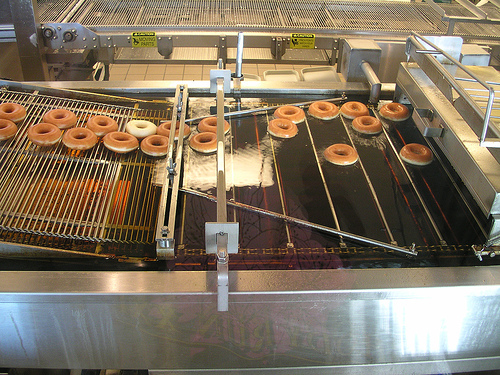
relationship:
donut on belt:
[125, 120, 157, 139] [13, 77, 190, 238]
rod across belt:
[199, 69, 236, 275] [2, 93, 472, 258]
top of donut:
[311, 99, 337, 115] [307, 99, 339, 121]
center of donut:
[114, 134, 131, 144] [101, 130, 141, 153]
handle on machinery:
[410, 104, 444, 136] [398, 65, 475, 171]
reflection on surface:
[145, 294, 387, 360] [7, 289, 499, 371]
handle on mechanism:
[412, 108, 443, 137] [402, 37, 499, 265]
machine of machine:
[0, 0, 500, 82] [0, 0, 498, 57]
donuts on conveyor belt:
[1, 91, 440, 171] [1, 76, 473, 267]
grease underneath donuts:
[0, 84, 499, 272] [3, 97, 439, 183]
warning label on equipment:
[131, 31, 157, 48] [2, 0, 497, 373]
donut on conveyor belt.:
[0, 93, 184, 148] [0, 91, 173, 243]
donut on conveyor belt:
[28, 119, 66, 147] [9, 81, 439, 256]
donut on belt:
[127, 116, 157, 136] [0, 80, 172, 250]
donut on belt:
[268, 117, 298, 139] [171, 97, 491, 264]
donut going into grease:
[0, 102, 191, 156] [187, 108, 469, 266]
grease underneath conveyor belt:
[255, 147, 382, 210] [7, 87, 479, 254]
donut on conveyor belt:
[186, 129, 221, 154] [9, 81, 439, 256]